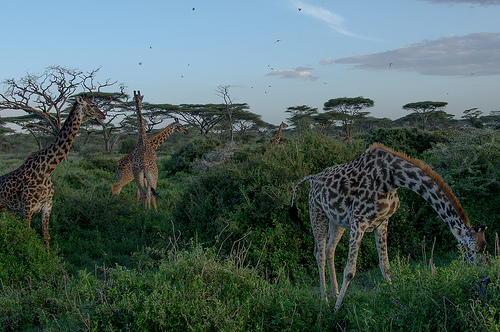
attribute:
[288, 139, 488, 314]
giraffe — bending, bending to eat, grazing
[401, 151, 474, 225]
neck — long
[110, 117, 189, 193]
giraffe — furthest to the left, standing, turned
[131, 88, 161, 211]
giraffe — standing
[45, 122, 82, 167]
visible neck — long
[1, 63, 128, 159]
tree — without leaves, tall, bare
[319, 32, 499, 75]
cloud — fluffy, very large, white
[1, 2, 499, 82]
sky — cloudy, blue, pale blue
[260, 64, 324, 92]
cloud — white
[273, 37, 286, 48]
bird — flying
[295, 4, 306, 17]
bird — flying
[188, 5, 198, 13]
bird — flying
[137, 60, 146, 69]
bird — flying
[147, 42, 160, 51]
bird — flying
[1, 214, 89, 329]
bush — green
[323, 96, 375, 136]
tree — tall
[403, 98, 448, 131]
tree — tall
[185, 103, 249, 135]
tree — tall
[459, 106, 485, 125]
small green tree — in the distance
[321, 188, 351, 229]
tummy — part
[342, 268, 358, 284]
knee — part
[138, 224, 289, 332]
plant — part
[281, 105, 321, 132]
shade tree — tall